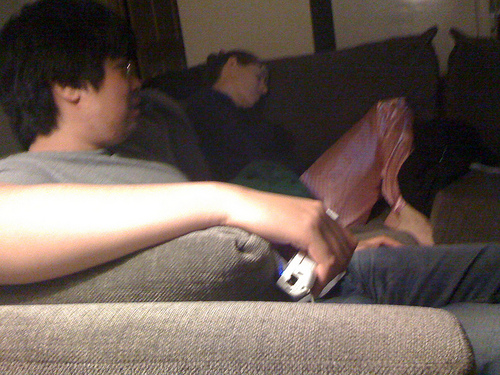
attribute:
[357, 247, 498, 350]
jeans — blue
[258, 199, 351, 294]
controller — white